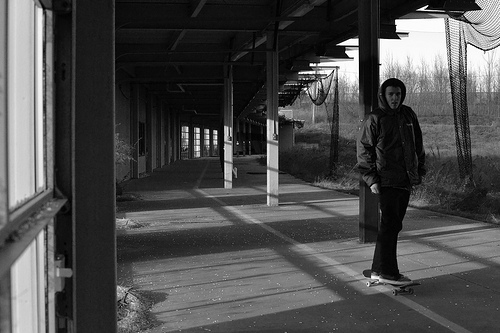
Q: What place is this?
A: It is a sidewalk.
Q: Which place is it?
A: It is a sidewalk.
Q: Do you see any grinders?
A: No, there are no grinders.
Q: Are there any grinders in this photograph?
A: No, there are no grinders.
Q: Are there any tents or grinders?
A: No, there are no grinders or tents.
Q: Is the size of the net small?
A: Yes, the net is small.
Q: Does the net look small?
A: Yes, the net is small.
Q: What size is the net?
A: The net is small.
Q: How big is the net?
A: The net is small.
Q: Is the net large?
A: No, the net is small.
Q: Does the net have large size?
A: No, the net is small.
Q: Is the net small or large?
A: The net is small.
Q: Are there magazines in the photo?
A: No, there are no magazines.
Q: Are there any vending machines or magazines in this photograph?
A: No, there are no magazines or vending machines.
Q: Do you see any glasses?
A: No, there are no glasses.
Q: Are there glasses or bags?
A: No, there are no glasses or bags.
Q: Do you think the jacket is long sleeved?
A: Yes, the jacket is long sleeved.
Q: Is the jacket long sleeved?
A: Yes, the jacket is long sleeved.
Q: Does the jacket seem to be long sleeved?
A: Yes, the jacket is long sleeved.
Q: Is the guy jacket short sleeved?
A: No, the jacket is long sleeved.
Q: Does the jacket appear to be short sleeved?
A: No, the jacket is long sleeved.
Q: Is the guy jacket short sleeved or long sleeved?
A: The jacket is long sleeved.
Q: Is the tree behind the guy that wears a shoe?
A: Yes, the tree is behind the guy.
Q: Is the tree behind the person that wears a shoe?
A: Yes, the tree is behind the guy.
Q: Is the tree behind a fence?
A: No, the tree is behind the guy.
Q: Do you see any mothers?
A: No, there are no mothers.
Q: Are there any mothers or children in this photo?
A: No, there are no mothers or children.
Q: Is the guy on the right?
A: Yes, the guy is on the right of the image.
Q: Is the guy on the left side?
A: No, the guy is on the right of the image.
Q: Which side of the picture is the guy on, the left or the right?
A: The guy is on the right of the image.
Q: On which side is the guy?
A: The guy is on the right of the image.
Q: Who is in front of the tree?
A: The guy is in front of the tree.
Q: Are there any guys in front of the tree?
A: Yes, there is a guy in front of the tree.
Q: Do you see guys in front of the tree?
A: Yes, there is a guy in front of the tree.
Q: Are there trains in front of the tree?
A: No, there is a guy in front of the tree.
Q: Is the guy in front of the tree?
A: Yes, the guy is in front of the tree.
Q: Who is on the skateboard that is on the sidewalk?
A: The guy is on the skateboard.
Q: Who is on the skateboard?
A: The guy is on the skateboard.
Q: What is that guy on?
A: The guy is on the skateboard.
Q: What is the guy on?
A: The guy is on the skateboard.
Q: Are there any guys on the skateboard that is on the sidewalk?
A: Yes, there is a guy on the skateboard.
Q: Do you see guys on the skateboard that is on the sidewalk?
A: Yes, there is a guy on the skateboard.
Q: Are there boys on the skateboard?
A: No, there is a guy on the skateboard.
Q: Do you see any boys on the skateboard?
A: No, there is a guy on the skateboard.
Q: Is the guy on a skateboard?
A: Yes, the guy is on a skateboard.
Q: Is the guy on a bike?
A: No, the guy is on a skateboard.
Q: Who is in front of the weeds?
A: The guy is in front of the weeds.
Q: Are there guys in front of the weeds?
A: Yes, there is a guy in front of the weeds.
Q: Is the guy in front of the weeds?
A: Yes, the guy is in front of the weeds.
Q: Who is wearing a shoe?
A: The guy is wearing a shoe.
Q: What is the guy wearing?
A: The guy is wearing a shoe.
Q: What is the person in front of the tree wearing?
A: The guy is wearing a shoe.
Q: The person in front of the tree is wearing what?
A: The guy is wearing a shoe.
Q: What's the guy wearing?
A: The guy is wearing a shoe.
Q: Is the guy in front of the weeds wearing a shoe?
A: Yes, the guy is wearing a shoe.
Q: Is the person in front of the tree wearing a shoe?
A: Yes, the guy is wearing a shoe.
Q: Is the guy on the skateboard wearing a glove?
A: No, the guy is wearing a shoe.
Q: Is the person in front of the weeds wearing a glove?
A: No, the guy is wearing a shoe.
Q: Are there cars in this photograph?
A: No, there are no cars.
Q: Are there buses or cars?
A: No, there are no cars or buses.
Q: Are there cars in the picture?
A: No, there are no cars.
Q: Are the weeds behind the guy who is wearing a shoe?
A: Yes, the weeds are behind the guy.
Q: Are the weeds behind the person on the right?
A: Yes, the weeds are behind the guy.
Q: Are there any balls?
A: No, there are no balls.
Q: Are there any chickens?
A: No, there are no chickens.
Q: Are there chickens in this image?
A: No, there are no chickens.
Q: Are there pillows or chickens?
A: No, there are no chickens or pillows.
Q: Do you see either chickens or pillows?
A: No, there are no chickens or pillows.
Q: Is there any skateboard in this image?
A: Yes, there is a skateboard.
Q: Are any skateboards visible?
A: Yes, there is a skateboard.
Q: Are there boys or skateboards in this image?
A: Yes, there is a skateboard.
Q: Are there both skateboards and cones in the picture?
A: No, there is a skateboard but no cones.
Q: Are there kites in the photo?
A: No, there are no kites.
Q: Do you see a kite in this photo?
A: No, there are no kites.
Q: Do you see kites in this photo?
A: No, there are no kites.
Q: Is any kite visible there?
A: No, there are no kites.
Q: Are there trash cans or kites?
A: No, there are no kites or trash cans.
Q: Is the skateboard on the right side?
A: Yes, the skateboard is on the right of the image.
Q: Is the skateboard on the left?
A: No, the skateboard is on the right of the image.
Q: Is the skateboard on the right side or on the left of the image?
A: The skateboard is on the right of the image.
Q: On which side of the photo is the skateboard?
A: The skateboard is on the right of the image.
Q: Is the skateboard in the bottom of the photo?
A: Yes, the skateboard is in the bottom of the image.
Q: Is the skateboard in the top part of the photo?
A: No, the skateboard is in the bottom of the image.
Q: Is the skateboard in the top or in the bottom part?
A: The skateboard is in the bottom of the image.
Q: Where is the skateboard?
A: The skateboard is on the sidewalk.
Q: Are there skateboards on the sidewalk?
A: Yes, there is a skateboard on the sidewalk.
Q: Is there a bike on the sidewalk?
A: No, there is a skateboard on the sidewalk.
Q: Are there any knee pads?
A: No, there are no knee pads.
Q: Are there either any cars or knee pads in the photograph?
A: No, there are no knee pads or cars.